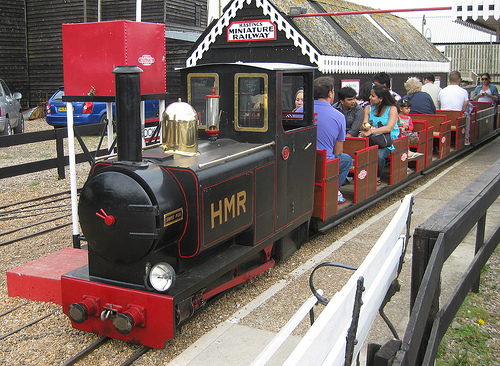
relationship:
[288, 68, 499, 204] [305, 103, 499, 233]
people in cars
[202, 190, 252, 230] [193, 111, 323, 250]
hmr on side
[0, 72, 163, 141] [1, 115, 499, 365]
cars on gravel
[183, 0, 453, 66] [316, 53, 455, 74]
roof has detailing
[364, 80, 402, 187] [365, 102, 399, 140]
woman has outfit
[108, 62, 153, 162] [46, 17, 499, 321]
smokestack on train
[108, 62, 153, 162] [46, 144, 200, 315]
smokestack on front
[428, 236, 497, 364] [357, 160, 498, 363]
grass near fence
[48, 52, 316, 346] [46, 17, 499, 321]
engine for train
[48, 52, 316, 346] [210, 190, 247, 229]
engine has hmr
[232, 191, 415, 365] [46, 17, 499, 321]
bench next to train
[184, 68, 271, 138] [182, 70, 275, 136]
windows have trim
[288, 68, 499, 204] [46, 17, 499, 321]
people on train